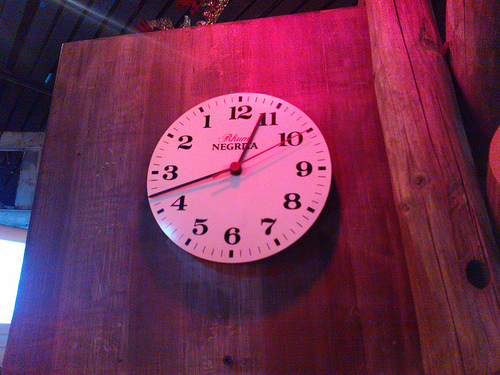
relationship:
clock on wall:
[145, 90, 335, 265] [8, 4, 425, 370]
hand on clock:
[213, 132, 300, 184] [145, 90, 335, 265]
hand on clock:
[151, 162, 245, 196] [145, 90, 335, 265]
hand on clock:
[230, 112, 265, 173] [145, 90, 335, 265]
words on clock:
[210, 132, 256, 150] [145, 90, 335, 265]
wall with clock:
[8, 4, 425, 370] [145, 90, 335, 265]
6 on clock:
[224, 223, 241, 243] [145, 90, 335, 265]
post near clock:
[363, 1, 498, 374] [145, 90, 335, 265]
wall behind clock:
[8, 4, 425, 370] [145, 90, 335, 265]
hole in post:
[467, 262, 488, 288] [363, 1, 498, 374]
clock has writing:
[145, 90, 335, 265] [212, 141, 258, 149]